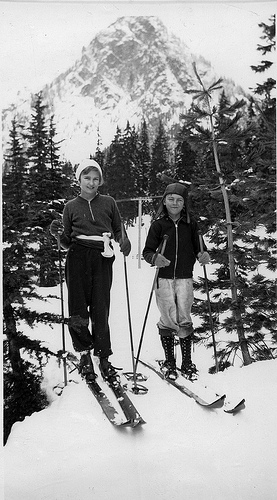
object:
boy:
[50, 158, 131, 376]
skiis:
[67, 350, 135, 431]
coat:
[143, 214, 206, 279]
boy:
[141, 181, 210, 381]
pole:
[138, 195, 141, 268]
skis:
[132, 353, 226, 412]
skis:
[156, 315, 246, 424]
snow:
[0, 0, 277, 499]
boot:
[157, 322, 177, 381]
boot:
[181, 336, 195, 375]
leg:
[154, 276, 174, 361]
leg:
[174, 279, 194, 363]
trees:
[137, 115, 149, 220]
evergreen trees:
[0, 43, 276, 254]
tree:
[182, 63, 272, 365]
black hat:
[153, 184, 190, 224]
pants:
[65, 243, 114, 359]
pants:
[154, 278, 193, 338]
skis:
[87, 342, 147, 428]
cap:
[74, 158, 104, 185]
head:
[74, 159, 101, 195]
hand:
[152, 254, 171, 269]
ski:
[122, 233, 169, 394]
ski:
[60, 345, 147, 426]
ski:
[133, 339, 244, 415]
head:
[163, 183, 188, 215]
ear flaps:
[153, 192, 167, 219]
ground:
[0, 43, 277, 499]